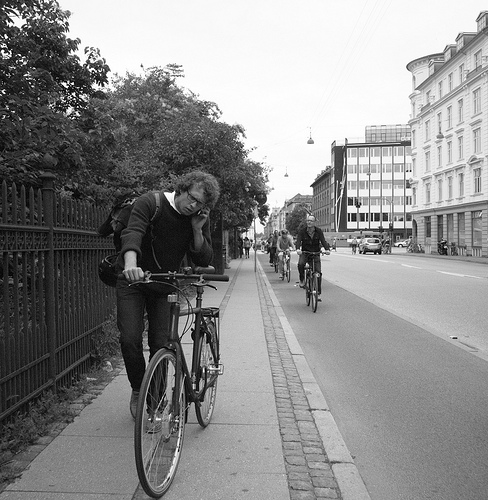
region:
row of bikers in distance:
[265, 230, 292, 280]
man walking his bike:
[98, 173, 227, 496]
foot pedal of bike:
[199, 359, 224, 402]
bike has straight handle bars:
[135, 270, 231, 289]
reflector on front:
[166, 290, 179, 303]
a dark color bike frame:
[171, 304, 201, 363]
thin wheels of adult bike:
[134, 348, 184, 499]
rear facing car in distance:
[358, 235, 381, 253]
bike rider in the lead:
[297, 214, 324, 305]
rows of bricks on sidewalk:
[282, 429, 320, 470]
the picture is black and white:
[41, 73, 476, 494]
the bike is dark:
[107, 241, 266, 495]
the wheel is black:
[121, 344, 185, 493]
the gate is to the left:
[10, 196, 138, 421]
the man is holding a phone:
[155, 156, 228, 246]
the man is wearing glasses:
[170, 177, 207, 219]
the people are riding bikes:
[259, 195, 338, 338]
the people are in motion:
[238, 193, 332, 325]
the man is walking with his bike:
[81, 159, 259, 457]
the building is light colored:
[400, 33, 485, 252]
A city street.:
[242, 171, 486, 448]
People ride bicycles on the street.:
[256, 204, 336, 307]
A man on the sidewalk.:
[95, 161, 245, 490]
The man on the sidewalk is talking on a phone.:
[88, 169, 237, 498]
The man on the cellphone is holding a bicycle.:
[90, 165, 242, 498]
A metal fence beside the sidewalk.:
[3, 163, 134, 468]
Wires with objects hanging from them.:
[270, 10, 396, 198]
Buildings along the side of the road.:
[263, 24, 486, 264]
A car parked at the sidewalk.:
[344, 228, 395, 256]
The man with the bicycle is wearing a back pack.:
[87, 162, 241, 496]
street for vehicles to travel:
[390, 249, 449, 310]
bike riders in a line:
[255, 215, 328, 297]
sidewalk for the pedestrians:
[222, 253, 265, 469]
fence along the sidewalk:
[5, 178, 166, 355]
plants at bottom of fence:
[6, 402, 47, 426]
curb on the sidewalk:
[313, 412, 354, 458]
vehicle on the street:
[357, 226, 389, 258]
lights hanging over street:
[270, 127, 321, 185]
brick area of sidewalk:
[286, 463, 326, 491]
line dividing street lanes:
[397, 254, 448, 284]